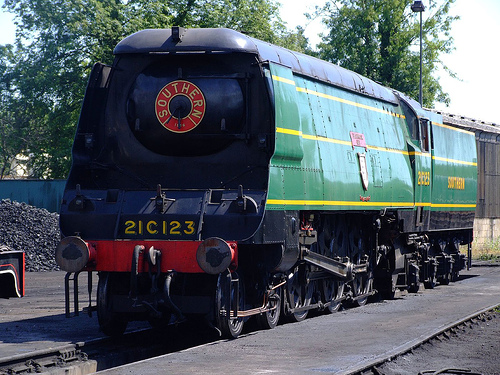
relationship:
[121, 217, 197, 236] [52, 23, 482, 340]
letters numbers on train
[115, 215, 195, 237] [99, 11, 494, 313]
train number on train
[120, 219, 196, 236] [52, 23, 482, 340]
numbers on train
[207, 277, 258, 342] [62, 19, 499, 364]
wheel on train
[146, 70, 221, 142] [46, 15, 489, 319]
circle logo on train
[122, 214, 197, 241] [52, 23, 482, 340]
number on train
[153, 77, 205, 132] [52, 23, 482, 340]
circle on back of train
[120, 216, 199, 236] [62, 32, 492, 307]
number of train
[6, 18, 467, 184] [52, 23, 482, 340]
trees behind train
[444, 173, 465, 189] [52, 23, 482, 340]
word painted on train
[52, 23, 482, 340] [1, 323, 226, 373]
train sitting on railroad track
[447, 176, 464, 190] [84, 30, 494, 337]
branding painted on train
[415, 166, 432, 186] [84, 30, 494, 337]
writing painted on train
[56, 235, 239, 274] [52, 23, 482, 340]
bumper painted on train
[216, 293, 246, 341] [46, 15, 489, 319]
wheel mounted on train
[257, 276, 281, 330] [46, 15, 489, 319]
wheel mounted on train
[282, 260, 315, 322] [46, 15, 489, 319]
wheel mounted on train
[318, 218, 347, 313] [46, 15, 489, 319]
wheel mounted on train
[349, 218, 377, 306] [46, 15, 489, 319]
wheel mounted on train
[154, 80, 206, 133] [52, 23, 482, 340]
circle logo mounted on train